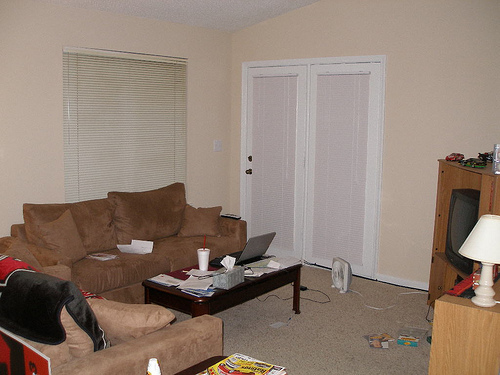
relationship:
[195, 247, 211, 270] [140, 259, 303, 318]
cup on table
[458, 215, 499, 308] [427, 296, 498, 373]
lamp sitting on table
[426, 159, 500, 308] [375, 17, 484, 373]
stand sitting sitting in corner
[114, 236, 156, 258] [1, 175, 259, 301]
paperwork sitting on couch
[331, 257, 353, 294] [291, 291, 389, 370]
box fan on floor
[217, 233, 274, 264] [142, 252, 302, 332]
computer on table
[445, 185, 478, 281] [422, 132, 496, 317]
television in tv stand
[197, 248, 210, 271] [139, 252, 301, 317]
cup on table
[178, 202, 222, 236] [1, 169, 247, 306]
pillow on couch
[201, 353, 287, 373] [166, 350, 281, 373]
magazines on end table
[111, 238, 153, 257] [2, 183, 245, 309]
paper on couch